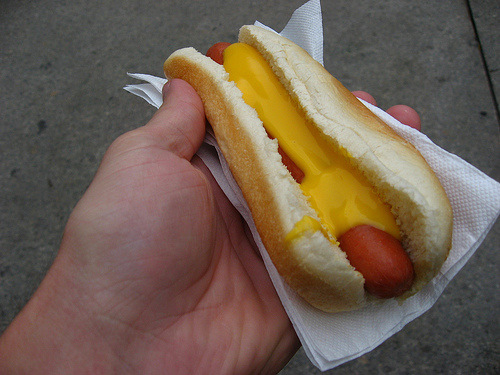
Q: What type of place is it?
A: It is a pavement.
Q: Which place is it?
A: It is a pavement.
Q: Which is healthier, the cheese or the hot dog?
A: The cheese is healthier than the hot dog.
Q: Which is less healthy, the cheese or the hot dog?
A: The hot dog is less healthy than the cheese.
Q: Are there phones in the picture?
A: No, there are no phones.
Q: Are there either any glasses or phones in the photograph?
A: No, there are no phones or glasses.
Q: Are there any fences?
A: No, there are no fences.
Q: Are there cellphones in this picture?
A: No, there are no cellphones.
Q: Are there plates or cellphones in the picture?
A: No, there are no cellphones or plates.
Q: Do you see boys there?
A: No, there are no boys.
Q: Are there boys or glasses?
A: No, there are no boys or glasses.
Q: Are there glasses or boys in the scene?
A: No, there are no boys or glasses.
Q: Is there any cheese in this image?
A: Yes, there is cheese.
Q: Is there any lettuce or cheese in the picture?
A: Yes, there is cheese.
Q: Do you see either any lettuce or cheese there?
A: Yes, there is cheese.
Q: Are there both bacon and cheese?
A: No, there is cheese but no bacon.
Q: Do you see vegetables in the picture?
A: No, there are no vegetables.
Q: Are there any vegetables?
A: No, there are no vegetables.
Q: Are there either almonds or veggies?
A: No, there are no veggies or almonds.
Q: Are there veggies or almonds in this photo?
A: No, there are no veggies or almonds.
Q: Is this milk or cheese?
A: This is cheese.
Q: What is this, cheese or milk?
A: This is cheese.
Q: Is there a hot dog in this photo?
A: Yes, there is a hot dog.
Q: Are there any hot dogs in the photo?
A: Yes, there is a hot dog.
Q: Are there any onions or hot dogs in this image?
A: Yes, there is a hot dog.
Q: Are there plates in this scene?
A: No, there are no plates.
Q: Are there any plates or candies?
A: No, there are no plates or candies.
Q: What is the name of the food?
A: The food is a hot dog.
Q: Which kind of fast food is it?
A: The food is a hot dog.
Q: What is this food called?
A: This is a hot dog.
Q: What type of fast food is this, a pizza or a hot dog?
A: This is a hot dog.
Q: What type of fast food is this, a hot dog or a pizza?
A: This is a hot dog.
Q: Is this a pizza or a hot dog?
A: This is a hot dog.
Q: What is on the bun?
A: The hot dog is on the bun.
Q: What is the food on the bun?
A: The food is a hot dog.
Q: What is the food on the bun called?
A: The food is a hot dog.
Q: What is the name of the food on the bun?
A: The food is a hot dog.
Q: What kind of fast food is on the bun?
A: The food is a hot dog.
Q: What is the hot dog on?
A: The hot dog is on the bun.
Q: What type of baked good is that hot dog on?
A: The hot dog is on the bun.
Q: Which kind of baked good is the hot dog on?
A: The hot dog is on the bun.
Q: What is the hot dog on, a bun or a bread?
A: The hot dog is on a bun.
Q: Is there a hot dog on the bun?
A: Yes, there is a hot dog on the bun.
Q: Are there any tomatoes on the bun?
A: No, there is a hot dog on the bun.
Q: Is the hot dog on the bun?
A: Yes, the hot dog is on the bun.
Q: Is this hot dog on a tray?
A: No, the hot dog is on the bun.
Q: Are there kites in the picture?
A: No, there are no kites.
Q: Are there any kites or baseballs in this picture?
A: No, there are no kites or baseballs.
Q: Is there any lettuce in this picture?
A: No, there is no lettuce.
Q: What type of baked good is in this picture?
A: The baked good is a bun.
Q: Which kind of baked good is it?
A: The food is a bun.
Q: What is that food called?
A: This is a bun.